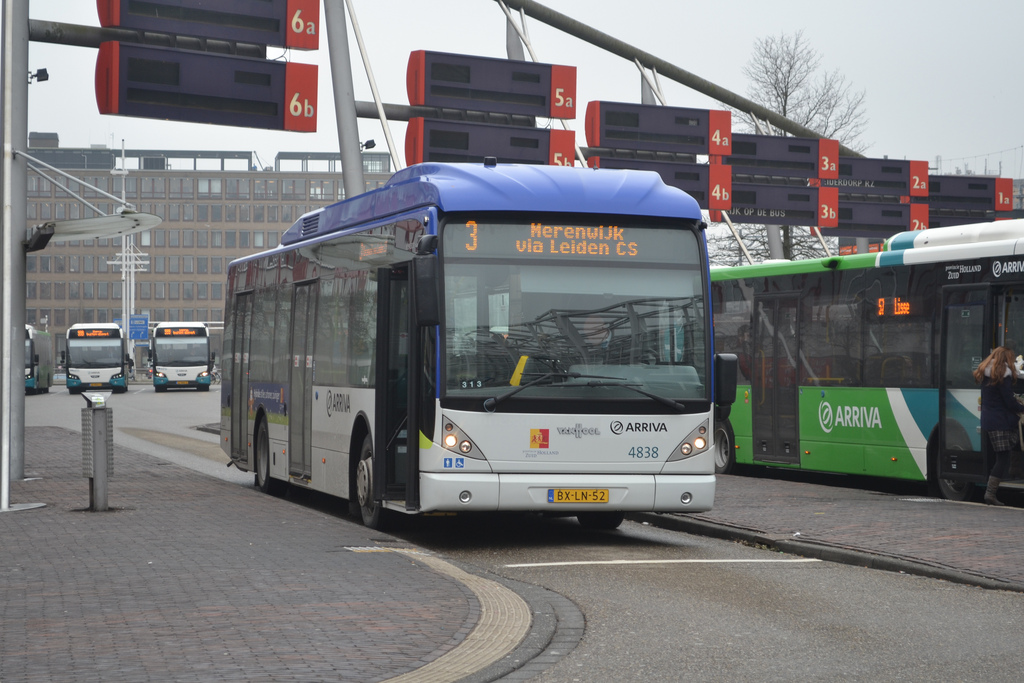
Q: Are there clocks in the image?
A: No, there are no clocks.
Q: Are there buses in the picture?
A: Yes, there is a bus.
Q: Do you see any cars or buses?
A: Yes, there is a bus.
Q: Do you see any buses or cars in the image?
A: Yes, there is a bus.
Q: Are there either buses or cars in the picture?
A: Yes, there is a bus.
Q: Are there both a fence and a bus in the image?
A: No, there is a bus but no fences.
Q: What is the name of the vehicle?
A: The vehicle is a bus.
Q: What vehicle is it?
A: The vehicle is a bus.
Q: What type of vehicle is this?
A: This is a bus.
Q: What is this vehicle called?
A: This is a bus.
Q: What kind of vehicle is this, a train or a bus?
A: This is a bus.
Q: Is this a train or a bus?
A: This is a bus.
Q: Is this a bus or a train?
A: This is a bus.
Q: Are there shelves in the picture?
A: No, there are no shelves.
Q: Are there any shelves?
A: No, there are no shelves.